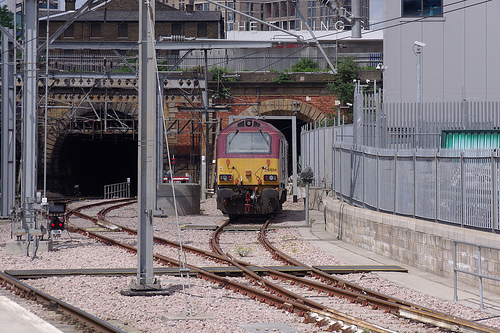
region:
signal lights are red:
[49, 220, 65, 230]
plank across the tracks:
[71, 262, 382, 268]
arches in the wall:
[49, 95, 351, 137]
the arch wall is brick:
[235, 93, 340, 132]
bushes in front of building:
[203, 35, 362, 95]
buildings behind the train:
[80, 3, 310, 226]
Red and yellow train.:
[215, 119, 288, 216]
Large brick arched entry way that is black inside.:
[38, 97, 139, 196]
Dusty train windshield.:
[225, 130, 270, 155]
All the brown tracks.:
[2, 197, 491, 332]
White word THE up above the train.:
[224, 19, 258, 31]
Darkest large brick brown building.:
[40, 1, 225, 41]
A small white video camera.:
[412, 39, 425, 52]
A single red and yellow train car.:
[215, 118, 289, 218]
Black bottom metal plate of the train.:
[215, 184, 277, 217]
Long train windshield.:
[224, 129, 271, 153]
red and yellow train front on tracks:
[213, 109, 295, 223]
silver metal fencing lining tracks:
[296, 67, 498, 233]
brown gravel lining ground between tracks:
[3, 197, 488, 325]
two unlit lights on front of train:
[212, 172, 281, 184]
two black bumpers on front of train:
[218, 188, 278, 214]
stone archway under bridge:
[39, 96, 144, 198]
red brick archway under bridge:
[173, 97, 340, 214]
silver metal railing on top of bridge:
[35, 36, 340, 73]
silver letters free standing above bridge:
[220, 15, 346, 38]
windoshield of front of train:
[223, 131, 273, 153]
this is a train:
[191, 85, 308, 222]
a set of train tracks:
[72, 194, 446, 326]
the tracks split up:
[113, 200, 393, 323]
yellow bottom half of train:
[211, 150, 290, 193]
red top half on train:
[214, 111, 282, 156]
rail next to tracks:
[108, 5, 193, 302]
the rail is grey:
[126, 0, 180, 298]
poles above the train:
[185, 0, 360, 68]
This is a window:
[394, 153, 416, 218]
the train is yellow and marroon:
[216, 118, 288, 219]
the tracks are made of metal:
[0, 195, 499, 331]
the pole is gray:
[131, 0, 162, 291]